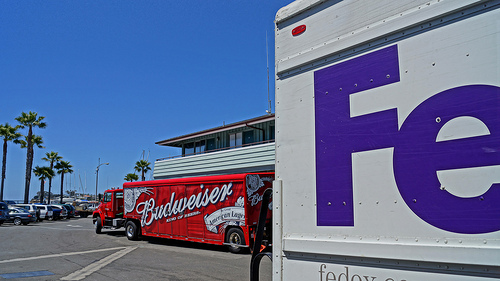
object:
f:
[312, 44, 399, 227]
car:
[35, 205, 53, 219]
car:
[49, 204, 76, 217]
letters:
[136, 181, 233, 228]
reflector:
[290, 24, 306, 36]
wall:
[160, 161, 252, 167]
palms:
[13, 110, 47, 126]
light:
[105, 162, 109, 165]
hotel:
[152, 112, 275, 179]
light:
[105, 162, 110, 165]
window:
[228, 130, 244, 149]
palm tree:
[32, 165, 57, 205]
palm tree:
[0, 122, 25, 202]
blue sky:
[54, 91, 182, 135]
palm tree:
[40, 151, 63, 205]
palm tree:
[53, 160, 73, 204]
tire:
[125, 221, 139, 240]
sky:
[1, 0, 273, 75]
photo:
[0, 0, 500, 281]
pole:
[95, 171, 99, 204]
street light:
[94, 158, 110, 208]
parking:
[34, 204, 77, 223]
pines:
[133, 160, 153, 182]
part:
[273, 0, 500, 80]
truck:
[249, 0, 500, 281]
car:
[3, 207, 36, 226]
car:
[11, 203, 38, 217]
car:
[48, 205, 68, 219]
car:
[75, 202, 94, 218]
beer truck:
[91, 172, 275, 254]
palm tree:
[11, 110, 47, 204]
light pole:
[95, 158, 110, 202]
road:
[0, 225, 96, 281]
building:
[151, 113, 275, 180]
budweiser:
[136, 181, 234, 228]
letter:
[392, 84, 500, 235]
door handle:
[249, 188, 273, 281]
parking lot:
[0, 201, 93, 228]